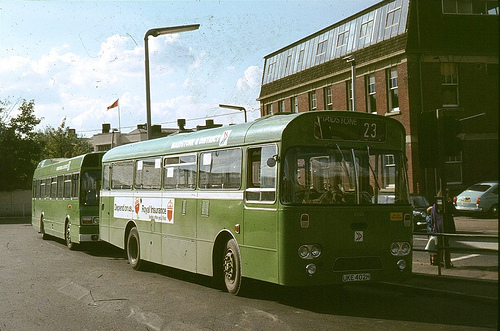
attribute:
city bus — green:
[97, 119, 427, 294]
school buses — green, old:
[33, 95, 418, 294]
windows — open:
[244, 144, 266, 190]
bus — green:
[101, 112, 413, 250]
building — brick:
[259, 0, 498, 117]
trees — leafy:
[12, 110, 81, 155]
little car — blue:
[453, 175, 499, 219]